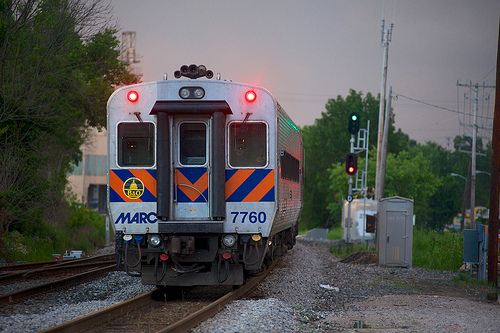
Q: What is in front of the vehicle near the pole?
A: The road is in front of the train.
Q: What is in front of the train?
A: The road is in front of the train.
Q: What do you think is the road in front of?
A: The road is in front of the train.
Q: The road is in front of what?
A: The road is in front of the train.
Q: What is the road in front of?
A: The road is in front of the train.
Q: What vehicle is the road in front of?
A: The road is in front of the train.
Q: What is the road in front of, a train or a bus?
A: The road is in front of a train.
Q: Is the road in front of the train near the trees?
A: Yes, the road is in front of the train.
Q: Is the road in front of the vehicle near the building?
A: Yes, the road is in front of the train.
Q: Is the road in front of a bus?
A: No, the road is in front of the train.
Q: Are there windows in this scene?
A: Yes, there are windows.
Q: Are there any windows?
A: Yes, there are windows.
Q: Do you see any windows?
A: Yes, there are windows.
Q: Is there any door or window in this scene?
A: Yes, there are windows.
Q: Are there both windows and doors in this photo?
A: Yes, there are both windows and a door.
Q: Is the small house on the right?
A: Yes, the house is on the right of the image.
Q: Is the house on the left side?
A: No, the house is on the right of the image.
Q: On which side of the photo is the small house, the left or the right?
A: The house is on the right of the image.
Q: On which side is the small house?
A: The house is on the right of the image.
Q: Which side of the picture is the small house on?
A: The house is on the right of the image.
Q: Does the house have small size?
A: Yes, the house is small.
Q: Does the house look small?
A: Yes, the house is small.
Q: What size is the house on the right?
A: The house is small.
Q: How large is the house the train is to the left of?
A: The house is small.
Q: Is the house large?
A: No, the house is small.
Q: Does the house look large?
A: No, the house is small.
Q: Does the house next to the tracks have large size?
A: No, the house is small.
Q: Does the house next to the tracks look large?
A: No, the house is small.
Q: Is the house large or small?
A: The house is small.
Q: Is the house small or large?
A: The house is small.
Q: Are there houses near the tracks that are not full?
A: Yes, there is a house near the train tracks.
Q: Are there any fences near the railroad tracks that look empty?
A: No, there is a house near the tracks.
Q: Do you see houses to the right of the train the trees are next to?
A: Yes, there is a house to the right of the train.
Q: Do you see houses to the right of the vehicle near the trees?
A: Yes, there is a house to the right of the train.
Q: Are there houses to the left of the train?
A: No, the house is to the right of the train.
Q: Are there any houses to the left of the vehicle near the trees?
A: No, the house is to the right of the train.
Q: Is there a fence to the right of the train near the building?
A: No, there is a house to the right of the train.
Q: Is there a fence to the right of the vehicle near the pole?
A: No, there is a house to the right of the train.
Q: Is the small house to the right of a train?
A: Yes, the house is to the right of a train.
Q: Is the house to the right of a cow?
A: No, the house is to the right of a train.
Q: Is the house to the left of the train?
A: No, the house is to the right of the train.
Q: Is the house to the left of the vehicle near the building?
A: No, the house is to the right of the train.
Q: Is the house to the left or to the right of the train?
A: The house is to the right of the train.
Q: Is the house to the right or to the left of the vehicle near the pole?
A: The house is to the right of the train.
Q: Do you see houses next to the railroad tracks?
A: Yes, there is a house next to the railroad tracks.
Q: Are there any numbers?
A: Yes, there are numbers.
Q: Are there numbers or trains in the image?
A: Yes, there are numbers.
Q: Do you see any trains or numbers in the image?
A: Yes, there are numbers.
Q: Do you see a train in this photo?
A: Yes, there is a train.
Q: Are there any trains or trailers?
A: Yes, there is a train.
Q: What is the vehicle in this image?
A: The vehicle is a train.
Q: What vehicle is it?
A: The vehicle is a train.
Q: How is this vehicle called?
A: That is a train.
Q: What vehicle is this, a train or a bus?
A: That is a train.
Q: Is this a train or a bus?
A: This is a train.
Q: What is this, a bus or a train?
A: This is a train.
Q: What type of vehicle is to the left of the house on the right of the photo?
A: The vehicle is a train.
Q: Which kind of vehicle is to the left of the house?
A: The vehicle is a train.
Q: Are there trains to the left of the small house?
A: Yes, there is a train to the left of the house.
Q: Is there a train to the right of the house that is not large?
A: No, the train is to the left of the house.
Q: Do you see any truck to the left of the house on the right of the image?
A: No, there is a train to the left of the house.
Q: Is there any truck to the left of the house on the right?
A: No, there is a train to the left of the house.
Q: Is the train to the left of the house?
A: Yes, the train is to the left of the house.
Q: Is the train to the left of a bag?
A: No, the train is to the left of the house.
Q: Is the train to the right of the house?
A: No, the train is to the left of the house.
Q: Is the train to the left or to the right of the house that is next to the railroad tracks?
A: The train is to the left of the house.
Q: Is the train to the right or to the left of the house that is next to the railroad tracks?
A: The train is to the left of the house.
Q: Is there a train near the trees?
A: Yes, there is a train near the trees.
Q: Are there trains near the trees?
A: Yes, there is a train near the trees.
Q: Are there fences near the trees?
A: No, there is a train near the trees.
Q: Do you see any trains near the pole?
A: Yes, there is a train near the pole.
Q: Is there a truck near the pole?
A: No, there is a train near the pole.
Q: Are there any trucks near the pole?
A: No, there is a train near the pole.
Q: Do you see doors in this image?
A: Yes, there is a door.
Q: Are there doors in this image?
A: Yes, there is a door.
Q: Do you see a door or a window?
A: Yes, there is a door.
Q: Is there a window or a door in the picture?
A: Yes, there is a door.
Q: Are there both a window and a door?
A: Yes, there are both a door and a window.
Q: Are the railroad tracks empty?
A: Yes, the railroad tracks are empty.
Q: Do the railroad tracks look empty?
A: Yes, the railroad tracks are empty.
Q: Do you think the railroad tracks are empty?
A: Yes, the railroad tracks are empty.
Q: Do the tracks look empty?
A: Yes, the tracks are empty.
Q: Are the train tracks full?
A: No, the train tracks are empty.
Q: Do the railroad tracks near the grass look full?
A: No, the railroad tracks are empty.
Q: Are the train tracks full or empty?
A: The train tracks are empty.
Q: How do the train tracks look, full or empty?
A: The train tracks are empty.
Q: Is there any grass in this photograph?
A: Yes, there is grass.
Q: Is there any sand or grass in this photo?
A: Yes, there is grass.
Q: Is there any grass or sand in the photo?
A: Yes, there is grass.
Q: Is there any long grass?
A: Yes, there is long grass.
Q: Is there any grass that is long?
A: Yes, there is grass that is long.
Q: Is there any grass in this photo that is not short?
A: Yes, there is long grass.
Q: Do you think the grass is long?
A: Yes, the grass is long.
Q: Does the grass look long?
A: Yes, the grass is long.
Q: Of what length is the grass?
A: The grass is long.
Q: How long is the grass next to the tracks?
A: The grass is long.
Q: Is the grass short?
A: No, the grass is long.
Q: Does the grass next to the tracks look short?
A: No, the grass is long.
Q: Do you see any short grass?
A: No, there is grass but it is long.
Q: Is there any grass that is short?
A: No, there is grass but it is long.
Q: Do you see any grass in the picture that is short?
A: No, there is grass but it is long.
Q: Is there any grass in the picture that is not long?
A: No, there is grass but it is long.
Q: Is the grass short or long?
A: The grass is long.